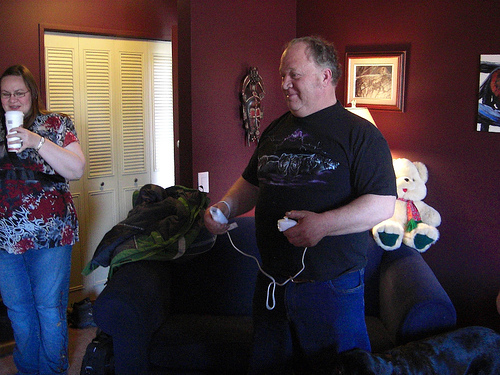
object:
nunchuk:
[276, 215, 296, 232]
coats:
[84, 183, 218, 268]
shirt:
[0, 105, 83, 255]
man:
[202, 37, 398, 373]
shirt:
[241, 100, 398, 281]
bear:
[371, 155, 441, 253]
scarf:
[396, 196, 422, 233]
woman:
[1, 63, 87, 375]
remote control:
[210, 206, 230, 226]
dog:
[322, 320, 500, 375]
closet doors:
[42, 31, 177, 313]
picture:
[353, 64, 393, 98]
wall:
[296, 4, 498, 328]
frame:
[342, 47, 406, 113]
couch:
[92, 217, 458, 375]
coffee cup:
[2, 110, 24, 153]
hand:
[8, 121, 42, 150]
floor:
[62, 326, 88, 372]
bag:
[79, 331, 109, 375]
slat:
[121, 160, 157, 168]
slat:
[82, 149, 112, 162]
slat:
[86, 98, 110, 108]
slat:
[122, 78, 145, 88]